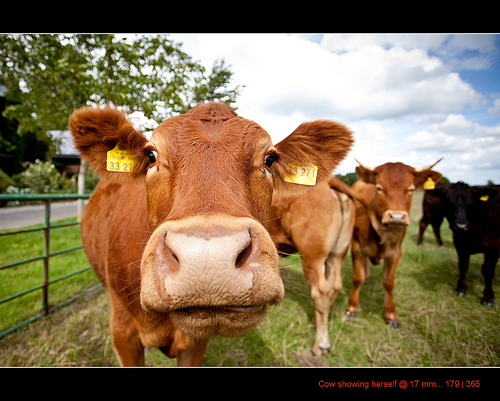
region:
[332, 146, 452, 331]
Cow on the grass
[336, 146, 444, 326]
Cow is on the grass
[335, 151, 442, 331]
Brown cow on the grass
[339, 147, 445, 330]
Brown cow is on the grass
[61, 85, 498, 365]
Cows on the grass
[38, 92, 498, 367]
Cows are on the grass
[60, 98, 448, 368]
Brown cows on the grass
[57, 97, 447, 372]
Brown cows are on the grass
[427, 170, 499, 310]
Black cow on the grass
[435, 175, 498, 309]
Black cow is on the grass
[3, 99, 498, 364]
five cows in a field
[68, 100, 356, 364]
brown cow has a tag in each ear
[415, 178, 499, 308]
two black cows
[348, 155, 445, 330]
brown cow has tag in left ear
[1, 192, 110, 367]
green metal fence between field and shoulder of road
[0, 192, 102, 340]
grassy shoulder beyond fence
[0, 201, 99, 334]
paved road beyond grass shoulder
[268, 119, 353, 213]
yellow tag in left ear reads "33 271"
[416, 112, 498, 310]
white clouds above cows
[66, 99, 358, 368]
cow with ear tags is in front of a cow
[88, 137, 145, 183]
Small yellow tag in a cows ear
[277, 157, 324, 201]
Small yellow tag in a cows ear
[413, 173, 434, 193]
Small yellow tag in a cows ear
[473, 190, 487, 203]
Small yellow tag in a cows ear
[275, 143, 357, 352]
Large brown cow standing in a field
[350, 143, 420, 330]
Large brown cow standing in a field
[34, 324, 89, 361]
Small patch of green grass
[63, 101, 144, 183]
the ear of a cow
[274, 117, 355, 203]
the ear of a cow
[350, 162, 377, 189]
the ear of a cow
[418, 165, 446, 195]
the ear of a cow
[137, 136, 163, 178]
the eye of a cow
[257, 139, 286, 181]
the eye of a cow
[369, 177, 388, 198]
the eye of a cow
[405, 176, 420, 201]
the eye of a cow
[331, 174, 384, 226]
the tail of a cow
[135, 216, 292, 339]
the nose and mouth of a cow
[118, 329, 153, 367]
leg of a cow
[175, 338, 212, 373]
leg of a cow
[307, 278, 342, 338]
leg of a cow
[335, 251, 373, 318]
leg of a cow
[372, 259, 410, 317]
leg of a cow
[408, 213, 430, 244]
leg of a cow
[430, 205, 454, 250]
leg of a cow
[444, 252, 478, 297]
leg of a cow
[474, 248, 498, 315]
leg of a cow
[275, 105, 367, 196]
ear of a cow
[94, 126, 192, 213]
the ear is tagged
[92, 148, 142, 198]
the tag is yellow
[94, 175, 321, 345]
the cow has a snout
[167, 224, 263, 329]
the snout is pink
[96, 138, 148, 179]
the yellow tag has letters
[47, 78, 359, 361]
the cow is brown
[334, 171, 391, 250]
the tail of cow is long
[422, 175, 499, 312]
the cow is black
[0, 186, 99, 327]
the fence is green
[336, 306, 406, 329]
the hooves are color black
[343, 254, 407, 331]
front legs of cow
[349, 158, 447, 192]
the ears are on side the head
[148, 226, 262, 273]
nose of the cow